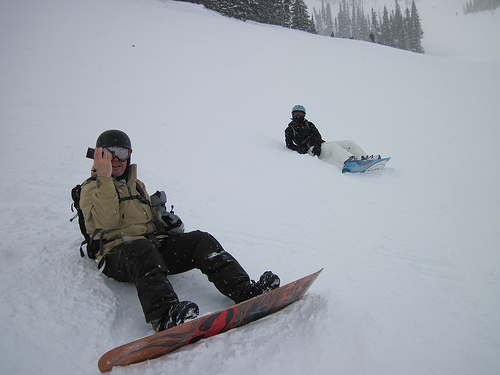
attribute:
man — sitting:
[78, 130, 282, 332]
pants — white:
[310, 138, 368, 161]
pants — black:
[98, 210, 252, 324]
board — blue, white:
[343, 157, 392, 173]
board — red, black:
[98, 267, 324, 374]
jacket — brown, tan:
[79, 165, 169, 267]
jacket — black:
[286, 120, 326, 155]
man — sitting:
[285, 105, 379, 167]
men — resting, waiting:
[80, 105, 380, 333]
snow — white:
[0, 0, 499, 374]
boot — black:
[156, 300, 199, 335]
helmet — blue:
[291, 104, 306, 115]